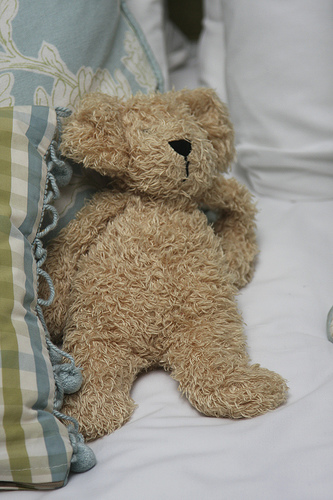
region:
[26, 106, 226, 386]
the teddy bear is brown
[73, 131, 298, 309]
the teddy bear is brown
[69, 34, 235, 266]
the teddy bear is brown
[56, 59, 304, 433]
soft cream color bear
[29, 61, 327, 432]
stuffed bear with two big soft ears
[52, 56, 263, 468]
soft bear with a black soft nose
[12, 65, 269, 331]
soft bear with two front paws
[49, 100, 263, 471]
soft bear with two soft back paws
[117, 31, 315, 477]
clean white sheet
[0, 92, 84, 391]
pillow with green on it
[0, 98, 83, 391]
pillow with blue fringe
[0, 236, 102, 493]
pillow with blue in the pring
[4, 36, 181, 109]
blue and white floral coverlet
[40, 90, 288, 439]
a furry tan teddy bear on a bed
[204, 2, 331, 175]
a white pillow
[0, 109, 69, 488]
a white blue and green checkered pillow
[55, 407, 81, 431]
blue yarn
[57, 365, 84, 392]
a bobble of made of blue yarn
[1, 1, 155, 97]
a blue green and white flowered pillow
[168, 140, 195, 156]
a black teddy bear nose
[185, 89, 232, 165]
a floppy toy bear ear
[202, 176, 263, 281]
a furry teddy bear arm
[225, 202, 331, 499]
a white bed sheet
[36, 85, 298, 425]
light brown furry teddy bear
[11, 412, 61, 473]
beige and blue patterned pillow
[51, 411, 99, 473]
baby blue fringe on pillow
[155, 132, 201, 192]
black nose on teddy bear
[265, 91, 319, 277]
clean white bed linens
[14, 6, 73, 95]
blue pillow with floral design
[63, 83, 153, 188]
big ears on teddy bear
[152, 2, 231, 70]
shadow between pillows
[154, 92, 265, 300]
bear leaning head on his paw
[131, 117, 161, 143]
bear eye hardly visible through fur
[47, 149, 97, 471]
Blue strings on the throw pillow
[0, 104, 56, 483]
Striped throw pillow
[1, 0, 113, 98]
Flower print on pillow case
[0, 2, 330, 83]
Pillows on the bed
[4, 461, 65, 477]
stitching on the pillow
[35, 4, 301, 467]
A teddy bear on the bed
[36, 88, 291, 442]
The teddy bear is brown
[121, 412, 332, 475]
Crease in the bed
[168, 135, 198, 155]
The black nose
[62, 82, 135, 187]
The ear of the teddy bear